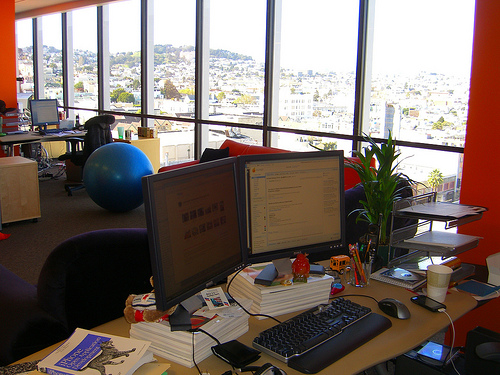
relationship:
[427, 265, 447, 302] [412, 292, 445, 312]
cup next to cell phone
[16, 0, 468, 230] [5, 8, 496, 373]
windows are inside room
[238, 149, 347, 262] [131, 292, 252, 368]
monitor on books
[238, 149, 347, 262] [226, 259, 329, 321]
monitor on books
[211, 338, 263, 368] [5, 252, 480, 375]
leather wallet on desk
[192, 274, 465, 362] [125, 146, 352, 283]
desk beneath computer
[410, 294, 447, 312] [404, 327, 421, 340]
cellphone on table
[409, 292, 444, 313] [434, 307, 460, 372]
cellphone with charger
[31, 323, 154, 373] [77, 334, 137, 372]
book with picture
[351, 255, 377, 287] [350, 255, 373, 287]
cup with cup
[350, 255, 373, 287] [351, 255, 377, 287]
cup with cup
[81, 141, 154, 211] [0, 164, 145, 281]
ball on carpet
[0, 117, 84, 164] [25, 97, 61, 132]
desk with computer moniter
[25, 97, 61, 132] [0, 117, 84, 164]
computer moniter on desk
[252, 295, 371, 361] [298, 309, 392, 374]
keyboard on arm rest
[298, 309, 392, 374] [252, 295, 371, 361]
arm rest on keyboard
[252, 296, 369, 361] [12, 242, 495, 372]
keyboard on desk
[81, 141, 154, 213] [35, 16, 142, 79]
ball by window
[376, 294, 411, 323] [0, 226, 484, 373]
computer mouse on desk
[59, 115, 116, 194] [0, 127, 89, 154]
chair near desk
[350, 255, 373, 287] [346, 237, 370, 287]
cup with pencils